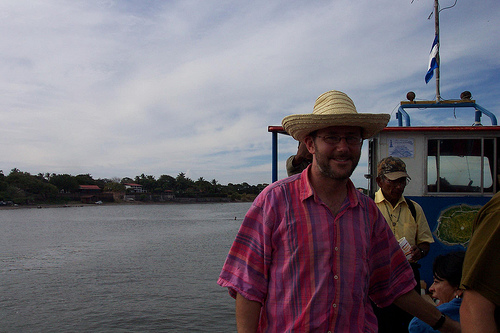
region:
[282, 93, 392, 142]
The beige hat the man in the pink shirt is wearing.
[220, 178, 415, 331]
The pink shirt the man is wearing.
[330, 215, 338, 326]
The buttons on the pink shirt.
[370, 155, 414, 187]
The hat the older man is wearing.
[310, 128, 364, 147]
The eyeglasses the man in the pink shirt is wearing.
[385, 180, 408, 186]
The eyeglasses the older man is wearing.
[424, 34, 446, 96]
The blue and white flag on the top of the boat's roof.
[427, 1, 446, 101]
The pole the flag is on.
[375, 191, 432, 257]
The yellow shirt the older man is wearing.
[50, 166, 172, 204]
The houses in the background.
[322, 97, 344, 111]
A woven hat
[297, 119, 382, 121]
Hat with wide brim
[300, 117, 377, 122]
The underside of a hat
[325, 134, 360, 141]
Eye glasses worn by man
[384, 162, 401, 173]
A man wearing a cap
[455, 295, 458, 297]
A woman with an earring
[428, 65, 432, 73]
A flag on a boat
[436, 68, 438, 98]
A pole with a flag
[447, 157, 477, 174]
Window on the boat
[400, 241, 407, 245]
A person holding a cup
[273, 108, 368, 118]
this is a hat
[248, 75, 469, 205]
the hat is made of straw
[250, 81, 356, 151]
the hat is yellow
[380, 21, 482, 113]
this is a flag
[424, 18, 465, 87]
the flag is blue and white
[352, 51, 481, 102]
this is a pole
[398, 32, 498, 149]
the pole is made of metal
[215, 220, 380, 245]
this is a shirt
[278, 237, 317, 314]
the shirt is red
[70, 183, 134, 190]
this is a mountain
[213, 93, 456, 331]
Man in straw hat and plaid shirt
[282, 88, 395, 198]
Man wearing glasses and straw hat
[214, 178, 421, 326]
A plaid button down shirt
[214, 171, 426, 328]
A pink and blue plaid button down shirt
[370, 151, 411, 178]
A camoflauge cap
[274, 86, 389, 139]
A tan straw hat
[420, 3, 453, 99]
A blue and white flag on a pole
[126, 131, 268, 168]
Wispy cirrus clouds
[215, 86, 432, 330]
Man wearing a plaid shirt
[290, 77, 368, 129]
man has straw hat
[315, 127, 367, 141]
man is wearing glasses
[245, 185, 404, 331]
red and pink shirt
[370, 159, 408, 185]
man has grey visor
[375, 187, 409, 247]
man has yellow shirt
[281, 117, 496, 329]
people on blue boat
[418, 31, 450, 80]
blue and white flag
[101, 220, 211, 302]
dark water is calm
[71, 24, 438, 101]
blue and white sky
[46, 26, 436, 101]
layers of clouds in sky